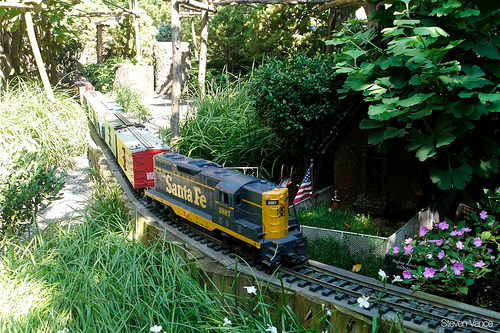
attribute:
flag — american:
[279, 154, 333, 219]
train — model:
[64, 67, 330, 282]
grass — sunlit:
[33, 227, 225, 320]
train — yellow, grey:
[142, 148, 309, 269]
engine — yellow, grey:
[144, 147, 311, 273]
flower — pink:
[400, 266, 412, 279]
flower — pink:
[420, 265, 437, 278]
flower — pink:
[390, 244, 400, 254]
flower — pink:
[401, 242, 413, 255]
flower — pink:
[432, 238, 443, 247]